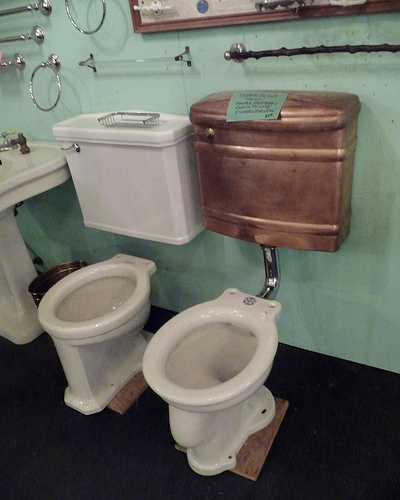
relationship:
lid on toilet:
[142, 290, 278, 401] [144, 286, 280, 476]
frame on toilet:
[249, 245, 284, 304] [138, 90, 372, 480]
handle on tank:
[51, 142, 85, 160] [37, 260, 144, 417]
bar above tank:
[78, 46, 191, 73] [52, 110, 205, 246]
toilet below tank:
[127, 93, 347, 474] [188, 88, 361, 253]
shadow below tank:
[142, 286, 281, 476] [52, 110, 205, 247]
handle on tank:
[190, 127, 215, 140] [189, 89, 360, 252]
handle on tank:
[60, 144, 80, 153] [52, 110, 205, 246]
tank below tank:
[37, 253, 157, 415] [52, 110, 205, 247]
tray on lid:
[96, 110, 160, 131] [51, 112, 189, 147]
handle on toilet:
[60, 144, 80, 153] [32, 108, 200, 415]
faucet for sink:
[0, 131, 14, 150] [0, 137, 70, 344]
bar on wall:
[77, 52, 195, 71] [0, 0, 400, 375]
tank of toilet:
[188, 88, 361, 253] [32, 108, 200, 415]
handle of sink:
[4, 136, 50, 160] [7, 143, 66, 196]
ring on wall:
[26, 51, 67, 112] [0, 0, 400, 375]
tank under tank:
[37, 253, 157, 415] [52, 110, 205, 247]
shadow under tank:
[142, 286, 281, 476] [188, 88, 361, 253]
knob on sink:
[1, 127, 15, 138] [1, 140, 74, 351]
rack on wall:
[223, 41, 400, 63] [0, 0, 400, 375]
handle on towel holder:
[223, 41, 245, 63] [224, 34, 394, 70]